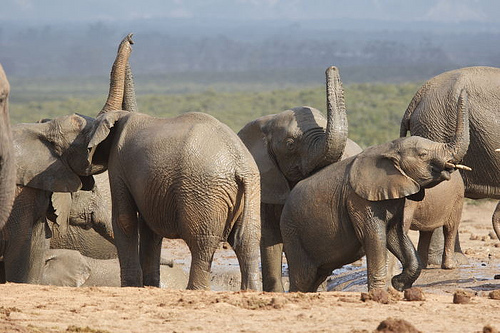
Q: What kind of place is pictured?
A: It is a field.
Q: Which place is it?
A: It is a field.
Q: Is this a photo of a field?
A: Yes, it is showing a field.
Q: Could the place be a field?
A: Yes, it is a field.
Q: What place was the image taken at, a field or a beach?
A: It was taken at a field.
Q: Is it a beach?
A: No, it is a field.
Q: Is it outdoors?
A: Yes, it is outdoors.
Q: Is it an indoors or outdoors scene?
A: It is outdoors.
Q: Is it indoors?
A: No, it is outdoors.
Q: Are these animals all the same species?
A: Yes, all the animals are elephants.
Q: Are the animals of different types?
A: No, all the animals are elephants.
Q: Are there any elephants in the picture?
A: Yes, there is an elephant.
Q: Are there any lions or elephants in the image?
A: Yes, there is an elephant.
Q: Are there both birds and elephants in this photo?
A: No, there is an elephant but no birds.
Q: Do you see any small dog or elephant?
A: Yes, there is a small elephant.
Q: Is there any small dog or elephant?
A: Yes, there is a small elephant.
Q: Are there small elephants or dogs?
A: Yes, there is a small elephant.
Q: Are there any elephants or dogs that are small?
A: Yes, the elephant is small.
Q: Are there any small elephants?
A: Yes, there is a small elephant.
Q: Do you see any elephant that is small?
A: Yes, there is an elephant that is small.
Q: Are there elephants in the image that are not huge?
A: Yes, there is a small elephant.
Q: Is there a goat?
A: No, there are no goats.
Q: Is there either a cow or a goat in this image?
A: No, there are no goats or cows.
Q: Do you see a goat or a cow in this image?
A: No, there are no goats or cows.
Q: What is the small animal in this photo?
A: The animal is an elephant.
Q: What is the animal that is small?
A: The animal is an elephant.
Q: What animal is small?
A: The animal is an elephant.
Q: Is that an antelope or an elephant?
A: That is an elephant.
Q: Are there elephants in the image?
A: Yes, there is an elephant.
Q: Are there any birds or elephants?
A: Yes, there is an elephant.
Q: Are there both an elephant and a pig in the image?
A: No, there is an elephant but no pigs.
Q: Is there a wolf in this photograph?
A: No, there are no wolves.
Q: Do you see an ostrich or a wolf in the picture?
A: No, there are no wolves or ostriches.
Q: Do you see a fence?
A: No, there are no fences.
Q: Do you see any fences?
A: No, there are no fences.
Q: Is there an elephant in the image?
A: Yes, there are elephants.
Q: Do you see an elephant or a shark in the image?
A: Yes, there are elephants.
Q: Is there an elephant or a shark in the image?
A: Yes, there are elephants.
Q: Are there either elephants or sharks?
A: Yes, there are elephants.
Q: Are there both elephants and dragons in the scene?
A: No, there are elephants but no dragons.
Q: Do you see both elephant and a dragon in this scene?
A: No, there are elephants but no dragons.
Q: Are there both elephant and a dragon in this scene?
A: No, there are elephants but no dragons.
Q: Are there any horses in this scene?
A: No, there are no horses.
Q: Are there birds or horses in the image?
A: No, there are no horses or birds.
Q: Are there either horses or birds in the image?
A: No, there are no horses or birds.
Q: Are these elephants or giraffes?
A: These are elephants.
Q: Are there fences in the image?
A: No, there are no fences.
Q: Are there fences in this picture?
A: No, there are no fences.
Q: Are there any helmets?
A: No, there are no helmets.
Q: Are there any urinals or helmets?
A: No, there are no helmets or urinals.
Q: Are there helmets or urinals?
A: No, there are no helmets or urinals.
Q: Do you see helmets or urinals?
A: No, there are no helmets or urinals.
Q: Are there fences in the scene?
A: No, there are no fences.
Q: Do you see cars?
A: No, there are no cars.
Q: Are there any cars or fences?
A: No, there are no cars or fences.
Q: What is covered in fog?
A: The trees are covered in fog.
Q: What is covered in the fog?
A: The trees are covered in fog.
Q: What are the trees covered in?
A: The trees are covered in fog.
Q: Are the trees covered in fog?
A: Yes, the trees are covered in fog.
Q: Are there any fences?
A: No, there are no fences.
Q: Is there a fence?
A: No, there are no fences.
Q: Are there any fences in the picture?
A: No, there are no fences.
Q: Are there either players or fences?
A: No, there are no fences or players.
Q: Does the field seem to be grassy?
A: Yes, the field is grassy.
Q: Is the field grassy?
A: Yes, the field is grassy.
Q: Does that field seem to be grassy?
A: Yes, the field is grassy.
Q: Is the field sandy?
A: No, the field is grassy.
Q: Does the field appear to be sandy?
A: No, the field is grassy.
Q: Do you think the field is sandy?
A: No, the field is grassy.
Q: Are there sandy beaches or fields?
A: No, there is a field but it is grassy.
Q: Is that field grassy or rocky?
A: The field is grassy.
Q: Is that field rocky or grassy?
A: The field is grassy.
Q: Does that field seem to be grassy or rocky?
A: The field is grassy.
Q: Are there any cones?
A: No, there are no cones.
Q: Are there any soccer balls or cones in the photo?
A: No, there are no cones or soccer balls.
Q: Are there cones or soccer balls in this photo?
A: No, there are no cones or soccer balls.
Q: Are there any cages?
A: No, there are no cages.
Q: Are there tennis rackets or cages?
A: No, there are no cages or tennis rackets.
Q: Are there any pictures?
A: No, there are no pictures.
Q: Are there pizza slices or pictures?
A: No, there are no pictures or pizza slices.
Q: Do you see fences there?
A: No, there are no fences.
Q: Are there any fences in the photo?
A: No, there are no fences.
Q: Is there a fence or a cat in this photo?
A: No, there are no fences or cats.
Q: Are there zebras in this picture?
A: No, there are no zebras.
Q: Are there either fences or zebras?
A: No, there are no zebras or fences.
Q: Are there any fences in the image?
A: No, there are no fences.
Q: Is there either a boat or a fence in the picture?
A: No, there are no fences or boats.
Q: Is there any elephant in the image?
A: Yes, there is an elephant.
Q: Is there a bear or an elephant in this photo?
A: Yes, there is an elephant.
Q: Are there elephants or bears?
A: Yes, there is an elephant.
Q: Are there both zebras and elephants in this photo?
A: No, there is an elephant but no zebras.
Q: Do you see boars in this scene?
A: No, there are no boars.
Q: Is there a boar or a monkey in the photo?
A: No, there are no boars or monkeys.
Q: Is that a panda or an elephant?
A: That is an elephant.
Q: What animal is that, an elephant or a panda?
A: That is an elephant.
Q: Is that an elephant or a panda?
A: That is an elephant.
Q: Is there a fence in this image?
A: No, there are no fences.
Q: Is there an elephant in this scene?
A: Yes, there is an elephant.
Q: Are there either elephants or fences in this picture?
A: Yes, there is an elephant.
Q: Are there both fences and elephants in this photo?
A: No, there is an elephant but no fences.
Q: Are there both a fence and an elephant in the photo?
A: No, there is an elephant but no fences.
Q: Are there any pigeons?
A: No, there are no pigeons.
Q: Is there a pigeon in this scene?
A: No, there are no pigeons.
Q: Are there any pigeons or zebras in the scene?
A: No, there are no pigeons or zebras.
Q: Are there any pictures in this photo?
A: No, there are no pictures.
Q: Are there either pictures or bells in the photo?
A: No, there are no pictures or bells.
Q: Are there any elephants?
A: Yes, there is an elephant.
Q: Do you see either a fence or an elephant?
A: Yes, there is an elephant.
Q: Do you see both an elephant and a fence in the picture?
A: No, there is an elephant but no fences.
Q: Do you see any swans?
A: No, there are no swans.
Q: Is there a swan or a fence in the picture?
A: No, there are no swans or fences.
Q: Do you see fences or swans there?
A: No, there are no swans or fences.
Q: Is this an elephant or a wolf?
A: This is an elephant.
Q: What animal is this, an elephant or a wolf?
A: This is an elephant.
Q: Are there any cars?
A: No, there are no cars.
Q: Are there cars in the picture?
A: No, there are no cars.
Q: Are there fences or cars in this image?
A: No, there are no cars or fences.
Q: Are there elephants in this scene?
A: Yes, there is an elephant.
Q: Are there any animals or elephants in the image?
A: Yes, there is an elephant.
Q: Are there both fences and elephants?
A: No, there is an elephant but no fences.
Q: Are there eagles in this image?
A: No, there are no eagles.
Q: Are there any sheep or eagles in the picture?
A: No, there are no eagles or sheep.